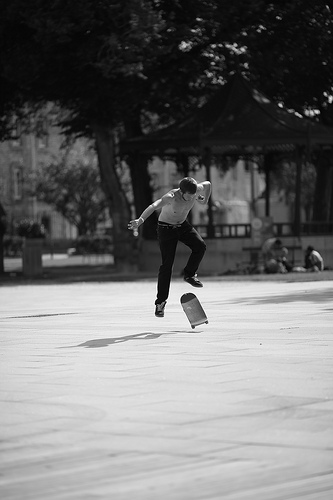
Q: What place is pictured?
A: It is a park.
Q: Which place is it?
A: It is a park.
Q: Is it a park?
A: Yes, it is a park.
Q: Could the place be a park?
A: Yes, it is a park.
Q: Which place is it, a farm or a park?
A: It is a park.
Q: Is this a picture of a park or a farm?
A: It is showing a park.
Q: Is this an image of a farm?
A: No, the picture is showing a park.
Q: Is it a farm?
A: No, it is a park.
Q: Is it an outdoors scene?
A: Yes, it is outdoors.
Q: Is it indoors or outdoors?
A: It is outdoors.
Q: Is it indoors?
A: No, it is outdoors.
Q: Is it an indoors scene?
A: No, it is outdoors.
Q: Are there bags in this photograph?
A: No, there are no bags.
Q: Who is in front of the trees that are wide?
A: The guy is in front of the trees.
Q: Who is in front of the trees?
A: The guy is in front of the trees.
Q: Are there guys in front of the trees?
A: Yes, there is a guy in front of the trees.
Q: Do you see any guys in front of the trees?
A: Yes, there is a guy in front of the trees.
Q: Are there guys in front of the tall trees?
A: Yes, there is a guy in front of the trees.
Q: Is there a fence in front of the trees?
A: No, there is a guy in front of the trees.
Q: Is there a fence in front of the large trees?
A: No, there is a guy in front of the trees.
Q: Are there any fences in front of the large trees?
A: No, there is a guy in front of the trees.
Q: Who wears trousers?
A: The guy wears trousers.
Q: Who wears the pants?
A: The guy wears trousers.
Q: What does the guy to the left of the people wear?
A: The guy wears trousers.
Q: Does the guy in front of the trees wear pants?
A: Yes, the guy wears pants.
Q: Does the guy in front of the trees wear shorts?
A: No, the guy wears pants.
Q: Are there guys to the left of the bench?
A: Yes, there is a guy to the left of the bench.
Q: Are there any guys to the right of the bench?
A: No, the guy is to the left of the bench.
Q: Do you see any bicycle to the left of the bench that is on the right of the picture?
A: No, there is a guy to the left of the bench.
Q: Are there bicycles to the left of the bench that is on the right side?
A: No, there is a guy to the left of the bench.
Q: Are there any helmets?
A: No, there are no helmets.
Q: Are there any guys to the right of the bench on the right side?
A: Yes, there are guys to the right of the bench.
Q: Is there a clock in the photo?
A: No, there are no clocks.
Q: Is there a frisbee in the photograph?
A: No, there are no frisbees.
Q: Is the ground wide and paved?
A: Yes, the ground is wide and paved.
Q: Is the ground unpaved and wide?
A: No, the ground is wide but paved.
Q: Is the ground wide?
A: Yes, the ground is wide.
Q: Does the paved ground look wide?
A: Yes, the ground is wide.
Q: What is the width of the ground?
A: The ground is wide.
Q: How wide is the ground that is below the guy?
A: The ground is wide.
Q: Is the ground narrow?
A: No, the ground is wide.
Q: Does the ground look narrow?
A: No, the ground is wide.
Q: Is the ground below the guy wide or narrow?
A: The ground is wide.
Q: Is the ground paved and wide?
A: Yes, the ground is paved and wide.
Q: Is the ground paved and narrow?
A: No, the ground is paved but wide.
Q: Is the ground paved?
A: Yes, the ground is paved.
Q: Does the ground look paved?
A: Yes, the ground is paved.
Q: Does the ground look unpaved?
A: No, the ground is paved.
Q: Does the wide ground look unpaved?
A: No, the ground is paved.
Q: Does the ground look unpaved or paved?
A: The ground is paved.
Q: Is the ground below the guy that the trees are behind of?
A: Yes, the ground is below the guy.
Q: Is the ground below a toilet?
A: No, the ground is below the guy.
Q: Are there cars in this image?
A: No, there are no cars.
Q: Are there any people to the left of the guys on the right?
A: Yes, there are people to the left of the guys.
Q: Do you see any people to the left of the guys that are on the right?
A: Yes, there are people to the left of the guys.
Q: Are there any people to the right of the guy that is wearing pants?
A: Yes, there are people to the right of the guy.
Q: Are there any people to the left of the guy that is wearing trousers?
A: No, the people are to the right of the guy.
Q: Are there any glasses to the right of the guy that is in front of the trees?
A: No, there are people to the right of the guy.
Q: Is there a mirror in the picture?
A: No, there are no mirrors.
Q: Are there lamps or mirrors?
A: No, there are no mirrors or lamps.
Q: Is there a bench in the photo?
A: Yes, there is a bench.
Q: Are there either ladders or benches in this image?
A: Yes, there is a bench.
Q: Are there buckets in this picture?
A: No, there are no buckets.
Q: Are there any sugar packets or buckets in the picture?
A: No, there are no buckets or sugar packets.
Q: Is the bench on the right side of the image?
A: Yes, the bench is on the right of the image.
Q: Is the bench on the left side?
A: No, the bench is on the right of the image.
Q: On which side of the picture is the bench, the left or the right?
A: The bench is on the right of the image.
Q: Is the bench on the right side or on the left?
A: The bench is on the right of the image.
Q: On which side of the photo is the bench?
A: The bench is on the right of the image.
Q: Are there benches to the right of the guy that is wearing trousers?
A: Yes, there is a bench to the right of the guy.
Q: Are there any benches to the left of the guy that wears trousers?
A: No, the bench is to the right of the guy.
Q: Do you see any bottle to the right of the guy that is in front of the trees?
A: No, there is a bench to the right of the guy.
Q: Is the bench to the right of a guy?
A: Yes, the bench is to the right of a guy.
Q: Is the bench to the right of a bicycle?
A: No, the bench is to the right of a guy.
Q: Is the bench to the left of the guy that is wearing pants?
A: No, the bench is to the right of the guy.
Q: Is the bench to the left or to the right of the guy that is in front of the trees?
A: The bench is to the right of the guy.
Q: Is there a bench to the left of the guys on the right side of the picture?
A: Yes, there is a bench to the left of the guys.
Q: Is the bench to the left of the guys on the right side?
A: Yes, the bench is to the left of the guys.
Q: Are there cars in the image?
A: No, there are no cars.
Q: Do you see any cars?
A: No, there are no cars.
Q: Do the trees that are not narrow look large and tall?
A: Yes, the trees are large and tall.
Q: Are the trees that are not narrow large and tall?
A: Yes, the trees are large and tall.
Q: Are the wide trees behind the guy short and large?
A: No, the trees are large but tall.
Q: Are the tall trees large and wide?
A: Yes, the trees are large and wide.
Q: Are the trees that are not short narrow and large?
A: No, the trees are large but wide.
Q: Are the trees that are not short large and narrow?
A: No, the trees are large but wide.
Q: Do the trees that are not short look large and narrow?
A: No, the trees are large but wide.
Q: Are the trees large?
A: Yes, the trees are large.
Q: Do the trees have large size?
A: Yes, the trees are large.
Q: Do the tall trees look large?
A: Yes, the trees are large.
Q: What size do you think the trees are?
A: The trees are large.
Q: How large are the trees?
A: The trees are large.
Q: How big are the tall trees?
A: The trees are large.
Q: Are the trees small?
A: No, the trees are large.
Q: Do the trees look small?
A: No, the trees are large.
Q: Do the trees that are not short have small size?
A: No, the trees are large.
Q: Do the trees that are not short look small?
A: No, the trees are large.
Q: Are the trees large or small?
A: The trees are large.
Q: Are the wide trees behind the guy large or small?
A: The trees are large.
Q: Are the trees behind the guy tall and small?
A: No, the trees are tall but large.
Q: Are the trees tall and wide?
A: Yes, the trees are tall and wide.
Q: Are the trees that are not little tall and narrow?
A: No, the trees are tall but wide.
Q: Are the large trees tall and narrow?
A: No, the trees are tall but wide.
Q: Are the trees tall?
A: Yes, the trees are tall.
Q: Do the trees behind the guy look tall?
A: Yes, the trees are tall.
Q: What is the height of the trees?
A: The trees are tall.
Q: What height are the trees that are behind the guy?
A: The trees are tall.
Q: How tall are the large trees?
A: The trees are tall.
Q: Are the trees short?
A: No, the trees are tall.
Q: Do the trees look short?
A: No, the trees are tall.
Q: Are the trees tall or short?
A: The trees are tall.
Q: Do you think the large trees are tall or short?
A: The trees are tall.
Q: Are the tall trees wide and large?
A: Yes, the trees are wide and large.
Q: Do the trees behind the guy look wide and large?
A: Yes, the trees are wide and large.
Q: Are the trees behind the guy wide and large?
A: Yes, the trees are wide and large.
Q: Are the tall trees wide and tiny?
A: No, the trees are wide but large.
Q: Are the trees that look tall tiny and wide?
A: No, the trees are wide but large.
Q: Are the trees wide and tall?
A: Yes, the trees are wide and tall.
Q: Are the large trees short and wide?
A: No, the trees are wide but tall.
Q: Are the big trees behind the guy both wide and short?
A: No, the trees are wide but tall.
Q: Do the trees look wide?
A: Yes, the trees are wide.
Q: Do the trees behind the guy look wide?
A: Yes, the trees are wide.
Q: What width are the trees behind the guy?
A: The trees are wide.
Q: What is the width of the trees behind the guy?
A: The trees are wide.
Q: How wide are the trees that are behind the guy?
A: The trees are wide.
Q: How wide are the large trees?
A: The trees are wide.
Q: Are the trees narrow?
A: No, the trees are wide.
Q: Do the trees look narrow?
A: No, the trees are wide.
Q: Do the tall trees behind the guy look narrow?
A: No, the trees are wide.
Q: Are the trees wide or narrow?
A: The trees are wide.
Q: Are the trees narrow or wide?
A: The trees are wide.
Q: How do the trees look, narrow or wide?
A: The trees are wide.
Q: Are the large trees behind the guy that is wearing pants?
A: Yes, the trees are behind the guy.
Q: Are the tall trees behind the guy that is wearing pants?
A: Yes, the trees are behind the guy.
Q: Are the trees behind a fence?
A: No, the trees are behind the guy.